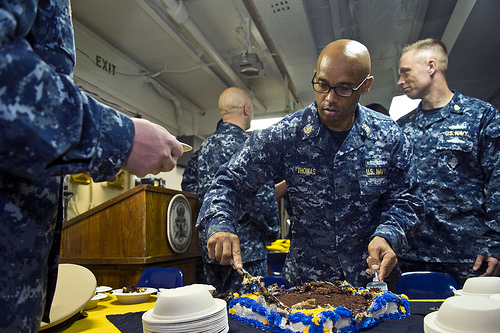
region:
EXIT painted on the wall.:
[91, 52, 121, 79]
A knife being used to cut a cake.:
[223, 253, 290, 314]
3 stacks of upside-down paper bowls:
[138, 273, 499, 331]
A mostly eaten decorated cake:
[226, 274, 409, 332]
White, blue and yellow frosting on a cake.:
[225, 278, 412, 332]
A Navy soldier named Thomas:
[192, 36, 426, 291]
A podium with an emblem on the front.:
[51, 179, 198, 289]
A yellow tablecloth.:
[37, 278, 175, 332]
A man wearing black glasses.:
[192, 32, 430, 292]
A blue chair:
[133, 262, 185, 295]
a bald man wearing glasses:
[310, 38, 374, 127]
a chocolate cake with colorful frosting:
[226, 278, 410, 330]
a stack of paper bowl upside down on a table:
[139, 288, 231, 330]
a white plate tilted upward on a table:
[36, 260, 98, 330]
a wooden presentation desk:
[61, 187, 204, 285]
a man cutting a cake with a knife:
[203, 233, 291, 311]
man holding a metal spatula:
[358, 238, 400, 303]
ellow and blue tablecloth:
[42, 289, 457, 331]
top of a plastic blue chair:
[137, 266, 184, 287]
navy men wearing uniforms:
[3, 1, 498, 329]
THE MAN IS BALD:
[308, 38, 373, 94]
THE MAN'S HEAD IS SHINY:
[307, 24, 375, 91]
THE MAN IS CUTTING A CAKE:
[221, 259, 295, 318]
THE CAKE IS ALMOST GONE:
[210, 273, 413, 330]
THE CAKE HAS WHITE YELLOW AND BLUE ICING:
[225, 263, 416, 331]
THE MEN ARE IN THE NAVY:
[1, 0, 499, 329]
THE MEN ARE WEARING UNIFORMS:
[3, 0, 499, 330]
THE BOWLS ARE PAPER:
[126, 275, 238, 332]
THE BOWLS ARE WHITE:
[132, 280, 242, 331]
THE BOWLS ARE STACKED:
[134, 275, 236, 332]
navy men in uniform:
[1, 2, 498, 326]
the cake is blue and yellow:
[231, 278, 415, 331]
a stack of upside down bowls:
[139, 280, 229, 331]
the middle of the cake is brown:
[271, 283, 376, 311]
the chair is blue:
[134, 262, 188, 289]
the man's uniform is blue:
[197, 105, 427, 302]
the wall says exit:
[92, 48, 122, 77]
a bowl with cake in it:
[108, 280, 155, 308]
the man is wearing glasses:
[304, 36, 376, 128]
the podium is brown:
[56, 180, 204, 287]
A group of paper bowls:
[140, 285, 230, 332]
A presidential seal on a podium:
[163, 194, 194, 254]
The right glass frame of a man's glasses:
[332, 82, 352, 97]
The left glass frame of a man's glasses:
[310, 75, 332, 96]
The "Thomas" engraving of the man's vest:
[287, 160, 318, 181]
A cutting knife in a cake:
[236, 270, 283, 311]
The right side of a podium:
[62, 181, 142, 266]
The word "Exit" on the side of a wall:
[90, 47, 126, 80]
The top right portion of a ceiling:
[275, 0, 498, 36]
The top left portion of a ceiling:
[77, 1, 281, 49]